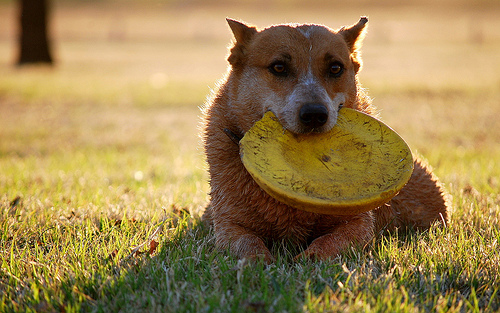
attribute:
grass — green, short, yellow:
[197, 287, 256, 309]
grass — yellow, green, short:
[48, 214, 160, 301]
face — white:
[244, 26, 348, 130]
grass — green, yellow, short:
[1, 0, 499, 312]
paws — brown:
[291, 249, 342, 269]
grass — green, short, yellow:
[15, 129, 178, 291]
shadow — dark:
[155, 263, 255, 293]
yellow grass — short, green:
[13, 104, 123, 228]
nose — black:
[297, 98, 332, 133]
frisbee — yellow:
[248, 121, 408, 201]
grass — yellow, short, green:
[99, 197, 169, 225]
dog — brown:
[168, 20, 482, 241]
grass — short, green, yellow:
[22, 207, 168, 304]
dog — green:
[200, 19, 450, 265]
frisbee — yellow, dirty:
[239, 104, 412, 212]